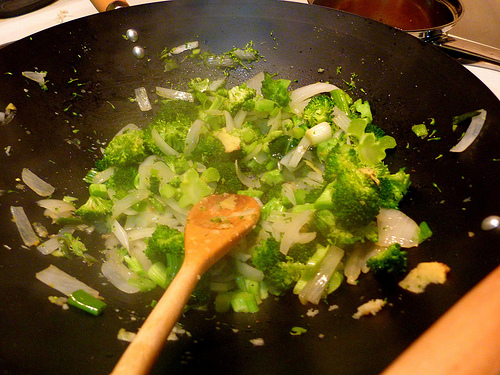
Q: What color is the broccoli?
A: Green.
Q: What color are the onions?
A: White.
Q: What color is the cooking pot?
A: Black.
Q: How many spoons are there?
A: One.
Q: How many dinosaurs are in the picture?
A: Zero.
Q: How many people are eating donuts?
A: Zero.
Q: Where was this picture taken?
A: In a kitchen.